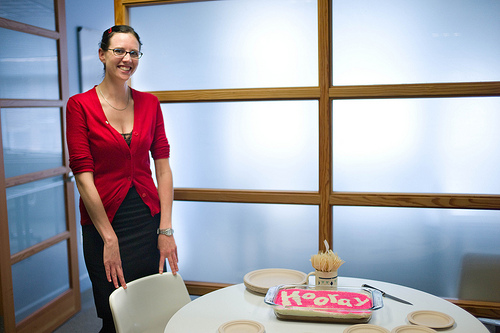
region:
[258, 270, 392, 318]
Cake with pink frosting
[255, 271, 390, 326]
Light blue glass cake pan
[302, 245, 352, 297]
Coffee mug filled with plastic forks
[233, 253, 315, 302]
Stack of large paper plates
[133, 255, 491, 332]
Round table with white tablecloth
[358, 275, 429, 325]
Metal serving knife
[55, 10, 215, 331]
Smiling woman behind chair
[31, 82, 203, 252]
Red cardigan with sleeves rolled up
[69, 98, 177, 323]
Knee length black dress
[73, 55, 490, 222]
Opaque office conference room windows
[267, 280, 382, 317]
cake with pink frosting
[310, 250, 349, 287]
jar of utensils on table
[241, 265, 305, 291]
paper plates on the table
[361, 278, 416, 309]
knife to cut the cake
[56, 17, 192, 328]
woman in a red sweater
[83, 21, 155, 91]
woman wearing a pair of glasses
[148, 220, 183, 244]
ladies watch on a wrist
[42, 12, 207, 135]
smiling woman wearing a necklace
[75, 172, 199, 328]
woman wearing a black skirt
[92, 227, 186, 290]
woman's hand touching a chair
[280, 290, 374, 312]
the word "Hooray" on a cake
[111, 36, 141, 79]
a smiling face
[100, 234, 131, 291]
a hand of a person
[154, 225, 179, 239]
a watch on a wrist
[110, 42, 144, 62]
glasses on a face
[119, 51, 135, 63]
a nose on a face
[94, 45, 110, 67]
an ear of a person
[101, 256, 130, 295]
fingers on a hand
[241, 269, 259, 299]
plates on a table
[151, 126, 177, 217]
an arm of a person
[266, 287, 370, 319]
a homemade cake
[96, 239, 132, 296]
the womans hand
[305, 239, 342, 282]
forks on the table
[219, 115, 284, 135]
a glass panel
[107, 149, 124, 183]
the womans is wearing a red shirt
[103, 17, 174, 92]
the woman is wearing glasses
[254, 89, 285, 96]
a piece of wood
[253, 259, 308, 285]
paper plates on the table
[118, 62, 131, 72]
the womans teeth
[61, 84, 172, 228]
A bright red, button-down sweater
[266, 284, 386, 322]
Cake with pink and white frosting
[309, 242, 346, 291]
Plastic silverware in a cup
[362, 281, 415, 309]
A knife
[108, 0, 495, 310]
Wood and glass office wall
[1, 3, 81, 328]
A door with 5 glass panels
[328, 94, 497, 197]
A frosted glass panel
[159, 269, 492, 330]
A round table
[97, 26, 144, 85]
A young woman with glasses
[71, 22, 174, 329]
A woman dressed in black and red